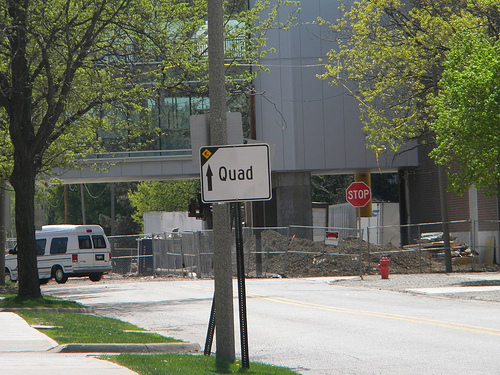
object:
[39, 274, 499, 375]
street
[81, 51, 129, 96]
grey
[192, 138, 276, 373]
direction sign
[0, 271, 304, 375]
street side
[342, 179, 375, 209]
stop sign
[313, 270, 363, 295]
corner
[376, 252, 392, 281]
hydrant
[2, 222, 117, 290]
van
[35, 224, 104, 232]
hi top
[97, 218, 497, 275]
fence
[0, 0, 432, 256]
building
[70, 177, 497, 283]
construction site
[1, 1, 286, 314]
tree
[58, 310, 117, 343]
green grass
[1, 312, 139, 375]
sidewalk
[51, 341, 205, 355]
curb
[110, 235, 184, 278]
chain link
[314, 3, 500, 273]
tree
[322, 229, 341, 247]
danger sign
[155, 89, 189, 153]
window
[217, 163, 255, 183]
quad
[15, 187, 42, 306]
trunk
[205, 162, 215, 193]
arrow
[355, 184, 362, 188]
red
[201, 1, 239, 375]
pole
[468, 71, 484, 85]
green leaves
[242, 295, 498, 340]
yellow lines